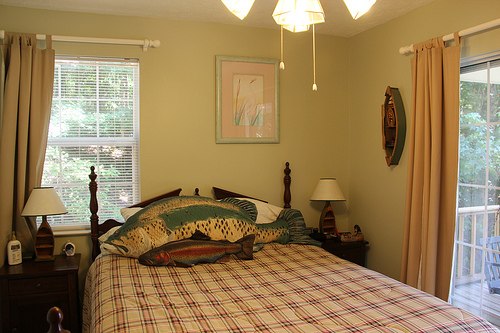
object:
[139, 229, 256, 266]
fish pillow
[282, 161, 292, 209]
post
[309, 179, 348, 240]
lamp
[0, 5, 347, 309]
wall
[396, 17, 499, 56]
curtainrod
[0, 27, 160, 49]
curtainrod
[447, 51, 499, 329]
window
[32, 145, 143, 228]
window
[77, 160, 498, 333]
bed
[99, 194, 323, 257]
fish pillow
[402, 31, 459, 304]
curtains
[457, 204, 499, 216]
woods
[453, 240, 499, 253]
woods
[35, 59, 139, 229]
mini blinds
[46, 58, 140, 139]
window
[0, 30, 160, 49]
rod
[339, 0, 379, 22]
fixture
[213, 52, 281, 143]
picture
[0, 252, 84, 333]
table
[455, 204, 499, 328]
balcony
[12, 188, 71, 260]
lamp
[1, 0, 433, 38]
ceiling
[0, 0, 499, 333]
bedroom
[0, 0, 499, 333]
room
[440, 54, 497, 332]
doorway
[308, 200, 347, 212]
shade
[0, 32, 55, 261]
curtain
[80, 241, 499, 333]
spread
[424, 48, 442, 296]
pleats